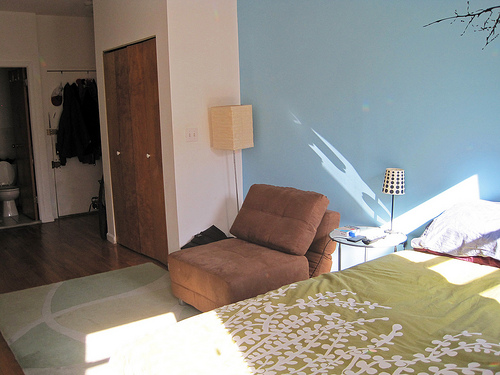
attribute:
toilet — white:
[1, 158, 23, 224]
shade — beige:
[205, 100, 260, 155]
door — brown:
[127, 41, 167, 265]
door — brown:
[96, 47, 136, 253]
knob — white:
[142, 152, 152, 160]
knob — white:
[111, 149, 121, 160]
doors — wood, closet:
[103, 36, 169, 263]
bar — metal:
[42, 63, 94, 75]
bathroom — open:
[1, 69, 38, 224]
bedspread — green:
[92, 248, 497, 374]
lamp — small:
[371, 157, 413, 239]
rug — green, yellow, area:
[1, 260, 190, 373]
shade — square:
[207, 101, 255, 151]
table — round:
[329, 224, 408, 271]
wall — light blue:
[220, 4, 447, 106]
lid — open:
[2, 159, 14, 189]